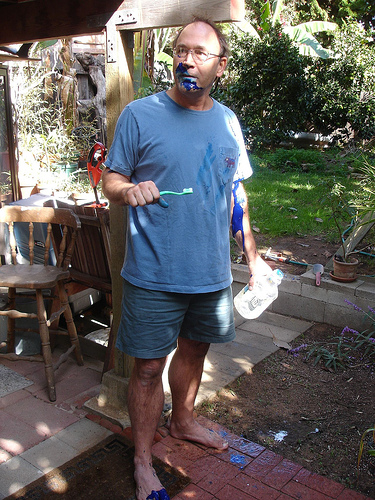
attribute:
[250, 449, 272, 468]
bricks — red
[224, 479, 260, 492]
bricks — red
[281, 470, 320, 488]
bricks — red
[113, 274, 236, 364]
shorts — grey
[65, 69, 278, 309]
shirt — blue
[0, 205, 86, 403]
chair — wood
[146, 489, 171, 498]
paint — blue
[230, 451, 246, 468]
paint — blue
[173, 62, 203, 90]
paint — blue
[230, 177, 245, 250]
paint — blue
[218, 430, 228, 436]
paint — blue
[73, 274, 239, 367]
shorts — gray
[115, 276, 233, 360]
shorts — blue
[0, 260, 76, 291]
seat — brown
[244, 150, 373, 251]
grass — green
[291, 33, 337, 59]
leaf — big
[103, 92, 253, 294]
shirt — blue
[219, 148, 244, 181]
pocket — small